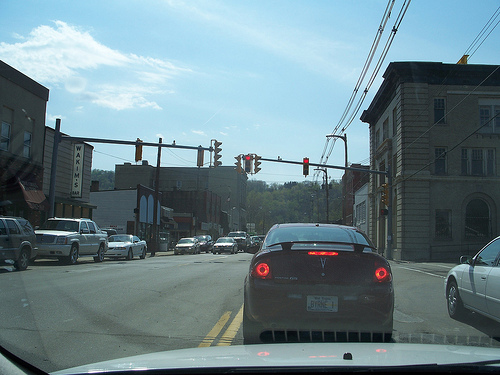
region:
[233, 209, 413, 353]
This is a car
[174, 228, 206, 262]
This is a car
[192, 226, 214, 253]
This is a car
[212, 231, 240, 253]
This is a car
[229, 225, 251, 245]
This is a car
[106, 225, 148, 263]
This is a car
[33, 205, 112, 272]
This is a car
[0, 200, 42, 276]
This is a car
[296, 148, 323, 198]
These are traffic lights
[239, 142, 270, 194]
These are traffic lights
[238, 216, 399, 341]
rear of small red car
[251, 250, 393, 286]
brakelights of small red car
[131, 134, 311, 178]
four traffic lights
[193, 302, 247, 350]
part of double yellow line in road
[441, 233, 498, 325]
part of silver car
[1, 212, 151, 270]
three parallel parked cars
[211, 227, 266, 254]
group of cars stopped at light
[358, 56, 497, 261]
part of old building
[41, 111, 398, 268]
traffic lights on metal bars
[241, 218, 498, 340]
two cars sitting at light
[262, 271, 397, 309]
brake lights of small black car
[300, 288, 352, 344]
license plate of small black car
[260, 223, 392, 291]
spoiler of black car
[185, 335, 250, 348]
double yellow lines on street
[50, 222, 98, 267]
white truck on curb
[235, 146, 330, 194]
traffic signals on pole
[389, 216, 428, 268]
brick columns at end of building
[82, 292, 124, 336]
street is gray asphalt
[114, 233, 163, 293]
small white car on street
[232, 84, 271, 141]
sky is light blue with thin clouds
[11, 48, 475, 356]
This is an outdoor setting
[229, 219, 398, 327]
this car has it's tail lights on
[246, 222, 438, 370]
this car is black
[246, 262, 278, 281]
these tail lights are red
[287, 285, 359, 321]
this is a license plate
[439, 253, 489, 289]
this car is white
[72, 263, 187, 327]
the street is made of pavement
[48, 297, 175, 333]
the pavement is gray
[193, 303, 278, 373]
the street lines are yellow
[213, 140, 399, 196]
these are traffic signals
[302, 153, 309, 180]
red traffic stop light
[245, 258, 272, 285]
red light on the back of car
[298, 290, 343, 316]
license plate on the back of the car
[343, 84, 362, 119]
electrical wires in the air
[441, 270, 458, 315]
tire on the gray car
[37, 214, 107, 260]
white truck parked on the side of road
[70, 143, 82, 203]
sign on the building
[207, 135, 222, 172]
stop lights on a pole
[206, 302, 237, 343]
yellow lines on the road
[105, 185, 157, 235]
brown and white building